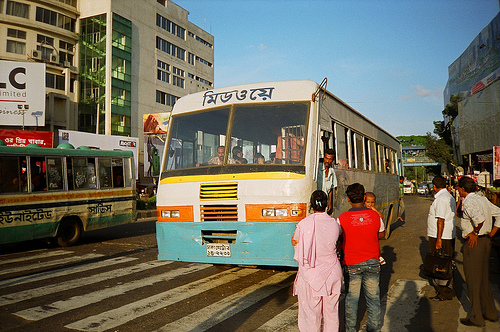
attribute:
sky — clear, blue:
[224, 17, 442, 110]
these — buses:
[2, 120, 421, 211]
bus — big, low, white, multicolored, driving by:
[143, 71, 418, 243]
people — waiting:
[285, 169, 493, 318]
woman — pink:
[297, 187, 333, 330]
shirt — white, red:
[415, 185, 454, 251]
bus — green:
[3, 133, 142, 237]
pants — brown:
[460, 236, 495, 331]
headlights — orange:
[152, 206, 295, 221]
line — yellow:
[99, 238, 156, 265]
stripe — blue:
[150, 227, 309, 268]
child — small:
[364, 186, 384, 210]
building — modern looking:
[78, 27, 231, 111]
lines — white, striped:
[9, 255, 291, 319]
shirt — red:
[340, 204, 387, 265]